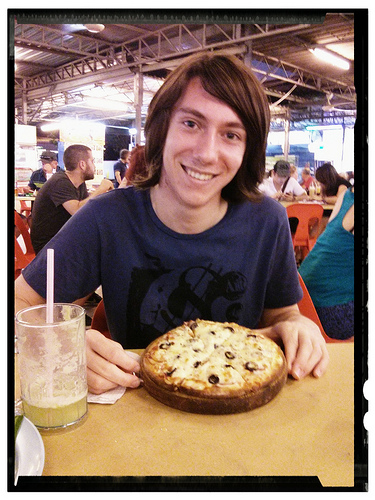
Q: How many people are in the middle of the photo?
A: 1.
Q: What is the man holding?
A: Food.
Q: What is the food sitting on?
A: The counter.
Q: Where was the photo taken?
A: Inside a restaurant.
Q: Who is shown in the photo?
A: A man.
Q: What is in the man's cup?
A: A drink.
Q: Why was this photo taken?
A: To show off the food.